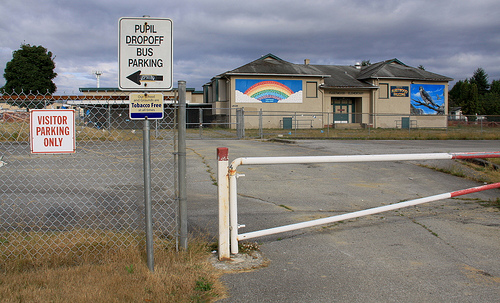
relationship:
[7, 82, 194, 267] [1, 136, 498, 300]
fence on concrete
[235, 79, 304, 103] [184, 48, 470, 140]
mural on building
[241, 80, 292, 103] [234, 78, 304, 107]
rainbow on mural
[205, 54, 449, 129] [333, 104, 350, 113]
building with a red sign on it sign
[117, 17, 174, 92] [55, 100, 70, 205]
board with a text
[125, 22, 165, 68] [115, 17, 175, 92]
text in a board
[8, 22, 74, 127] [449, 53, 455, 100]
tree on back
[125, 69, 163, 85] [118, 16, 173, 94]
black arrow on bottom of sign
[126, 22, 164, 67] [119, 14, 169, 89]
text on sign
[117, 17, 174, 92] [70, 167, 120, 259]
board on metal fence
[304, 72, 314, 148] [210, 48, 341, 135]
mural on a building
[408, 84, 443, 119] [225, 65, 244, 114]
mural on side of building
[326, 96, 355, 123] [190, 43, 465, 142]
doorway in a building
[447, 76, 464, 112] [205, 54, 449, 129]
tree to right of building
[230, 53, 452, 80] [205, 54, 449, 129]
roof of a building